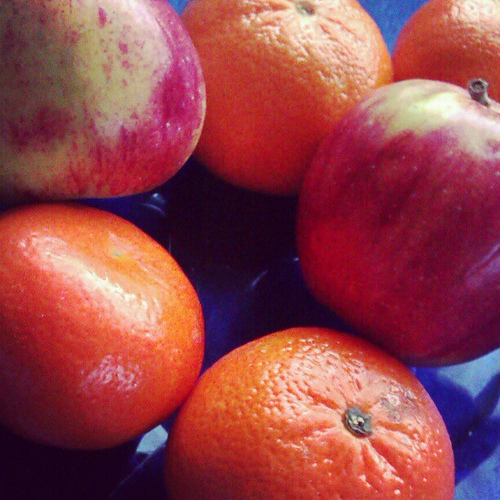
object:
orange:
[162, 326, 455, 500]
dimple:
[344, 407, 374, 437]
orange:
[175, 0, 396, 192]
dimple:
[291, 1, 318, 17]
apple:
[297, 76, 499, 367]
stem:
[468, 79, 490, 108]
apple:
[1, 0, 209, 203]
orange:
[3, 207, 204, 450]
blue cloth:
[0, 0, 499, 500]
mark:
[296, 380, 341, 414]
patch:
[362, 80, 500, 161]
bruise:
[381, 386, 419, 421]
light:
[22, 234, 163, 334]